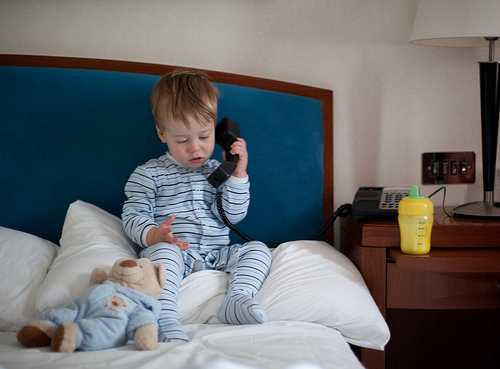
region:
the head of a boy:
[149, 66, 224, 172]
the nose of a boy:
[186, 133, 202, 155]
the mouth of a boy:
[185, 151, 205, 166]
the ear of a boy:
[153, 121, 168, 143]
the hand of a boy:
[144, 210, 194, 256]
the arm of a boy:
[116, 166, 161, 241]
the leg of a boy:
[213, 238, 275, 297]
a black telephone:
[202, 114, 250, 192]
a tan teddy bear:
[16, 243, 180, 360]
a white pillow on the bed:
[32, 191, 398, 355]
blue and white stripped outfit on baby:
[122, 149, 273, 343]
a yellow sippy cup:
[397, 185, 434, 256]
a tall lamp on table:
[391, 1, 499, 221]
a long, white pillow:
[38, 198, 401, 350]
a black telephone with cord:
[209, 114, 420, 248]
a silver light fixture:
[419, 148, 476, 184]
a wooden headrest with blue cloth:
[1, 54, 339, 251]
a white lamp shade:
[409, 1, 498, 51]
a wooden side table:
[341, 203, 498, 365]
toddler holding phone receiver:
[117, 73, 269, 340]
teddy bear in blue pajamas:
[16, 255, 164, 359]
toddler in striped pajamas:
[121, 72, 271, 346]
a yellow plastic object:
[397, 185, 432, 259]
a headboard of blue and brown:
[0, 52, 335, 249]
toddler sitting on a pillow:
[121, 71, 273, 340]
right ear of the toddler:
[152, 120, 169, 150]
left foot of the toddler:
[214, 289, 265, 334]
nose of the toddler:
[185, 137, 203, 155]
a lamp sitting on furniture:
[397, 2, 497, 224]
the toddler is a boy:
[120, 65, 277, 347]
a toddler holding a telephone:
[122, 67, 274, 342]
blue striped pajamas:
[121, 152, 273, 342]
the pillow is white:
[31, 193, 391, 348]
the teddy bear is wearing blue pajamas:
[18, 254, 169, 354]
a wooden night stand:
[336, 202, 499, 367]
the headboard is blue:
[3, 51, 340, 263]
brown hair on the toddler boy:
[142, 64, 222, 138]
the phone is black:
[215, 128, 245, 194]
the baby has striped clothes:
[144, 93, 288, 323]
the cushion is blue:
[256, 103, 322, 242]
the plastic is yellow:
[401, 195, 438, 245]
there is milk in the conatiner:
[392, 183, 438, 258]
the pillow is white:
[277, 244, 353, 324]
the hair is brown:
[156, 80, 213, 117]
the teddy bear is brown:
[21, 252, 176, 342]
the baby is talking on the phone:
[143, 82, 262, 334]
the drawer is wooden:
[360, 228, 497, 310]